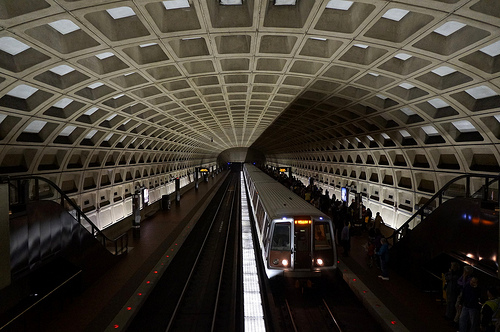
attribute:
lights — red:
[119, 253, 163, 321]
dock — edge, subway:
[66, 180, 178, 297]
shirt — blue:
[358, 232, 431, 265]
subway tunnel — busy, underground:
[6, 9, 493, 330]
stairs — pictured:
[7, 174, 130, 258]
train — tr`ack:
[243, 163, 339, 283]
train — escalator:
[218, 150, 343, 279]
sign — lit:
[292, 215, 312, 225]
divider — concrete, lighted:
[199, 143, 296, 328]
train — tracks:
[237, 157, 359, 274]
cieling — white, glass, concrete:
[224, 4, 470, 101]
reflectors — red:
[90, 269, 168, 320]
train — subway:
[232, 157, 349, 294]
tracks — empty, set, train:
[187, 195, 237, 296]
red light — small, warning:
[134, 290, 145, 298]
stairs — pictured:
[393, 168, 491, 246]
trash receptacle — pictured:
[159, 191, 172, 213]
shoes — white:
[378, 270, 389, 282]